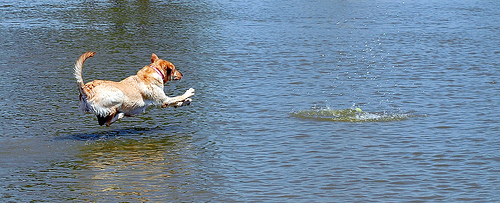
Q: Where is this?
A: On the water.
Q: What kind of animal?
A: Dog.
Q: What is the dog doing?
A: Playing.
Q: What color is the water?
A: Brown.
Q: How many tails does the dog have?
A: 1.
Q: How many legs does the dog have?
A: 4.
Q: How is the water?
A: Calm.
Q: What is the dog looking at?
A: A disturbance in the water.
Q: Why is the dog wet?
A: It's in the water.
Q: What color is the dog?
A: Tan and white.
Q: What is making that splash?
A: Where is the ball into the water.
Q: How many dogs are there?
A: 1.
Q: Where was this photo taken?
A: At a lake.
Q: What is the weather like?
A: Sunny.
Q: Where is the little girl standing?
A: There is no little girl.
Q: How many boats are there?
A: There are no boats.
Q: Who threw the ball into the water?
A: The dogs owner.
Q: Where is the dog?
A: In the air.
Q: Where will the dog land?
A: In the water.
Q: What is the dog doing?
A: Jumping.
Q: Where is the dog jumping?
A: Into the water.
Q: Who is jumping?
A: The dog.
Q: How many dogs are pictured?
A: One.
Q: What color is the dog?
A: Tan.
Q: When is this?
A: Daytime.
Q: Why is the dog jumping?
A: To get the toy.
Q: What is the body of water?
A: A lake.